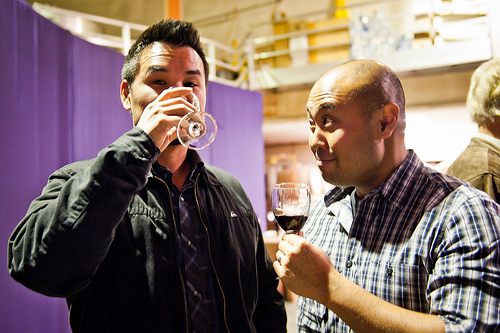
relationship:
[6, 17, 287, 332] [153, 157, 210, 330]
man in blue shirt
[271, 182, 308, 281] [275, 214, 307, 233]
glass contains wine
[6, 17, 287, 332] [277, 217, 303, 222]
man drinking wine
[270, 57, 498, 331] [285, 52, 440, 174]
man has head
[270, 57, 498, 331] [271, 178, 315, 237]
man holding glass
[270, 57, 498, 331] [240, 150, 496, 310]
man wearing shirt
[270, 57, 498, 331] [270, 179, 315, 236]
man drinking wine glass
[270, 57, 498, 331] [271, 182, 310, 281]
man holding glass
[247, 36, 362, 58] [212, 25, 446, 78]
rails of walkway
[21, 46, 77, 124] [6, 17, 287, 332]
wall behind man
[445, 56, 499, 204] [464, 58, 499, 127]
person has hair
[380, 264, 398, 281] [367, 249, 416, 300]
button on shirt pocket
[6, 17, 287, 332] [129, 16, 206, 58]
man with spiked hair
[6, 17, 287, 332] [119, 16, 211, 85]
man has spiked hair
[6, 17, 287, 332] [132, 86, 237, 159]
man drinking from glass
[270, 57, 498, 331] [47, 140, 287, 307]
man wearing jacket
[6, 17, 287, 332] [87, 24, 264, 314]
man drinking wine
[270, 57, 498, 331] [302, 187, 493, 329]
man in shirt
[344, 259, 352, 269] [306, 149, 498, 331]
button on shirt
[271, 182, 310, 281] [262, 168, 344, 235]
glass of wine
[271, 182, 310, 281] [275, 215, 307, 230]
glass of wine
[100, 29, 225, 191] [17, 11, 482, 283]
man in foreground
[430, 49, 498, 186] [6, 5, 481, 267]
person in background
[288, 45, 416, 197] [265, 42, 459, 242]
side view of head